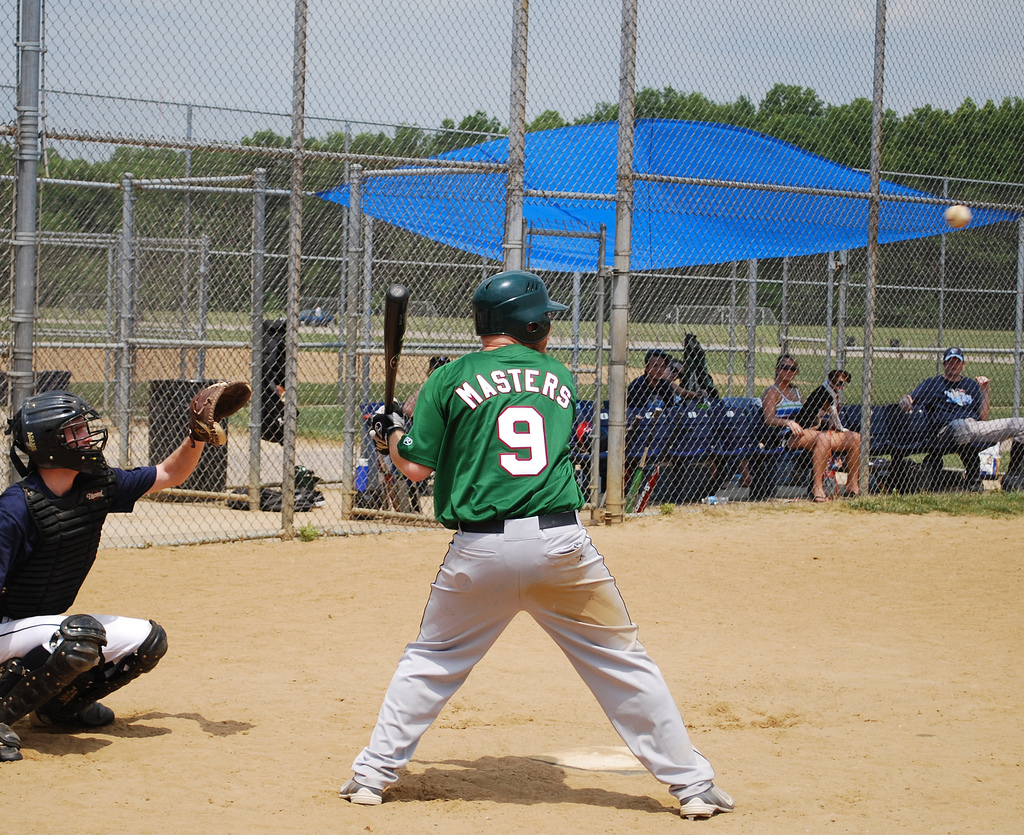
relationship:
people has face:
[759, 356, 867, 502] [774, 350, 797, 385]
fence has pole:
[0, 3, 1021, 507] [273, 4, 306, 532]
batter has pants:
[329, 265, 732, 814] [348, 503, 718, 798]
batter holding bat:
[329, 265, 732, 814] [353, 248, 434, 517]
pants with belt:
[348, 503, 718, 798] [449, 508, 583, 537]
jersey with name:
[402, 346, 594, 523] [449, 366, 571, 415]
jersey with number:
[402, 346, 594, 523] [494, 404, 551, 478]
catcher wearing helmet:
[0, 372, 252, 764] [3, 380, 124, 488]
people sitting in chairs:
[617, 342, 739, 485] [638, 349, 1017, 460]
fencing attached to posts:
[560, 142, 1006, 518] [558, 88, 719, 512]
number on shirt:
[496, 407, 542, 474] [414, 344, 583, 515]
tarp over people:
[317, 110, 1022, 272] [759, 356, 867, 502]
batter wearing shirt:
[329, 265, 732, 814] [430, 348, 599, 517]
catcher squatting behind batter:
[3, 379, 147, 640] [385, 232, 635, 577]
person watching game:
[762, 351, 868, 512] [653, 304, 911, 534]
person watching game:
[625, 339, 690, 403] [12, 122, 1017, 797]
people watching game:
[901, 345, 1019, 492] [18, 71, 1010, 733]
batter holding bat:
[439, 264, 573, 582] [357, 269, 412, 435]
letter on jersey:
[446, 354, 486, 419] [417, 345, 598, 542]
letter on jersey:
[471, 368, 503, 394] [423, 352, 600, 549]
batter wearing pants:
[329, 265, 732, 814] [348, 503, 718, 798]